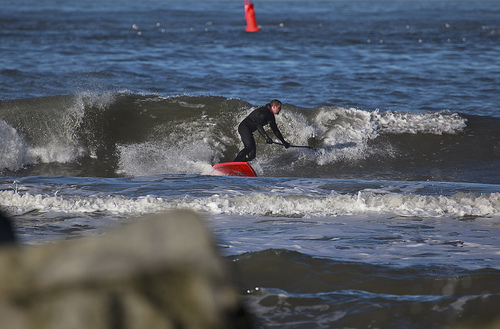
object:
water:
[0, 2, 494, 110]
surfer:
[233, 97, 290, 162]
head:
[269, 99, 283, 115]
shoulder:
[259, 106, 270, 113]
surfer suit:
[225, 104, 281, 164]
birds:
[132, 23, 143, 35]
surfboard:
[210, 160, 259, 178]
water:
[230, 186, 344, 259]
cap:
[316, 102, 468, 136]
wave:
[0, 90, 500, 188]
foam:
[0, 187, 500, 217]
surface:
[3, 211, 499, 267]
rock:
[0, 207, 253, 329]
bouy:
[242, 2, 263, 32]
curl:
[59, 89, 131, 141]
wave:
[0, 188, 500, 218]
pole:
[274, 141, 315, 149]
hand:
[262, 133, 291, 149]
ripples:
[0, 45, 498, 113]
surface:
[0, 42, 500, 117]